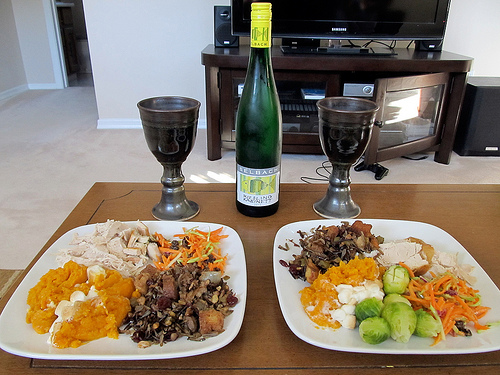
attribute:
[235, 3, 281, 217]
bottle — green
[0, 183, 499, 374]
table — brown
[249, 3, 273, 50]
cap — yellow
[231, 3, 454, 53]
television — black, flat screen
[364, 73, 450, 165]
door — glass, wood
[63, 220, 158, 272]
meat — white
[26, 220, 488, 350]
food — for two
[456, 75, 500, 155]
speaker — black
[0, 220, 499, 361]
plates — white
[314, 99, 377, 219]
goblet — brown, metal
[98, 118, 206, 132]
baseboard — white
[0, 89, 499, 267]
carpet — beige